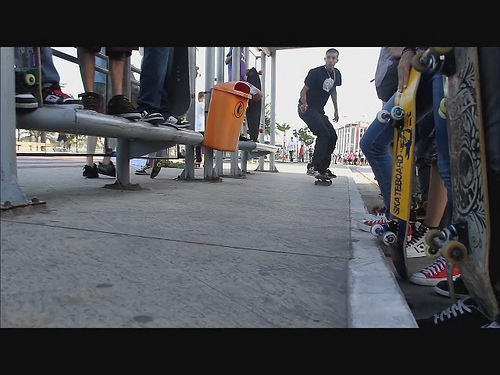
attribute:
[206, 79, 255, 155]
can — orange, trash, plastic, small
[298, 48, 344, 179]
man — riding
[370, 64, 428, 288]
skateboard — yellow, black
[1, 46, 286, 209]
railing — silver, grey, metal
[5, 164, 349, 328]
sidewalk — grey, concrete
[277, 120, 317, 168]
trees — far, green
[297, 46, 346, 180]
skateboarder — riding, leaning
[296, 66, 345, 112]
shirt — black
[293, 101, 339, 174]
pants — black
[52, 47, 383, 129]
sky — white, blue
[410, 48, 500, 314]
skateboard — black, white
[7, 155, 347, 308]
path — flat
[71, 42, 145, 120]
person — standing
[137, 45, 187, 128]
person — standing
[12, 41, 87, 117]
person — standing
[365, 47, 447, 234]
person — standing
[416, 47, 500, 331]
person — standing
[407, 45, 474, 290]
person — standing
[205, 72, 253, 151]
container — hanging, orange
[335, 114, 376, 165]
building — multi-floor, white, red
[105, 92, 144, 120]
shoe — black, clunky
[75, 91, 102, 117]
shoe — black, clunky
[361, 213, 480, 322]
sneakers — black, red, white, lined, skate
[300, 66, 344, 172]
clothing — dark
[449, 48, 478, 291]
drawing — detailed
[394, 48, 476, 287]
skateboarder — standing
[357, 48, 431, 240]
skateboarder — standing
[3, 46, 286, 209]
bench — metal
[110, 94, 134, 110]
laces — black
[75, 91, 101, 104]
laces — black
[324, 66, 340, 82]
chain — metal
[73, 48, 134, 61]
shorts — black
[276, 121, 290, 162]
tree — palm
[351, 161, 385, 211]
street — grey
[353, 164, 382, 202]
stripe — yellow